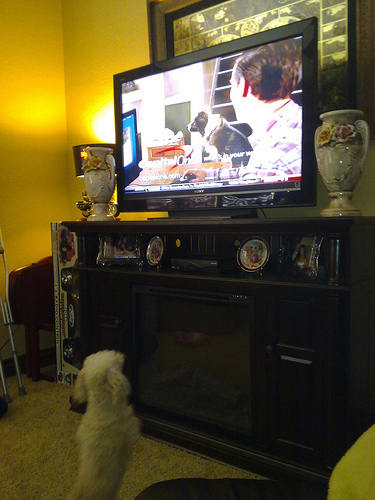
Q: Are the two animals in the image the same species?
A: Yes, all the animals are dogs.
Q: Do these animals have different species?
A: No, all the animals are dogs.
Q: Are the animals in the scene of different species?
A: No, all the animals are dogs.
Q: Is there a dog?
A: Yes, there is a dog.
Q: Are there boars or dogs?
A: Yes, there is a dog.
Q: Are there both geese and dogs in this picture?
A: No, there is a dog but no geese.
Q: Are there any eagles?
A: No, there are no eagles.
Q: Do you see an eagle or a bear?
A: No, there are no eagles or bears.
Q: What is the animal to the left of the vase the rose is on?
A: The animal is a dog.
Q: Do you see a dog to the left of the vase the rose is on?
A: Yes, there is a dog to the left of the vase.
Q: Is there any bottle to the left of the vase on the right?
A: No, there is a dog to the left of the vase.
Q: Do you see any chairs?
A: Yes, there is a chair.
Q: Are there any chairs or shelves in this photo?
A: Yes, there is a chair.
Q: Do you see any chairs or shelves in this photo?
A: Yes, there is a chair.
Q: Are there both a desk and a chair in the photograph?
A: No, there is a chair but no desks.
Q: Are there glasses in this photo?
A: No, there are no glasses.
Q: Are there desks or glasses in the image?
A: No, there are no glasses or desks.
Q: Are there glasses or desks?
A: No, there are no glasses or desks.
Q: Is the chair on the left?
A: Yes, the chair is on the left of the image.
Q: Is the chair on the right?
A: No, the chair is on the left of the image.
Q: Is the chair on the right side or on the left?
A: The chair is on the left of the image.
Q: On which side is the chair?
A: The chair is on the left of the image.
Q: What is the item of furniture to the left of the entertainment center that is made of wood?
A: The piece of furniture is a chair.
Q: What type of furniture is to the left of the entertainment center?
A: The piece of furniture is a chair.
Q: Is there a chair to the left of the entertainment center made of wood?
A: Yes, there is a chair to the left of the entertainment center.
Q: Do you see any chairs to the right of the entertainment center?
A: No, the chair is to the left of the entertainment center.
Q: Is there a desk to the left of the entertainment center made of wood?
A: No, there is a chair to the left of the entertainment center.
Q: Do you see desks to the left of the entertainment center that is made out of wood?
A: No, there is a chair to the left of the entertainment center.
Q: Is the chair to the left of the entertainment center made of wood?
A: Yes, the chair is to the left of the entertainment center.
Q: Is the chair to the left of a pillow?
A: No, the chair is to the left of the entertainment center.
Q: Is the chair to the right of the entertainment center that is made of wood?
A: No, the chair is to the left of the entertainment center.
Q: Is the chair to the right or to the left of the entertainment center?
A: The chair is to the left of the entertainment center.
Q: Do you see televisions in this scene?
A: Yes, there is a television.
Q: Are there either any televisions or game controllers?
A: Yes, there is a television.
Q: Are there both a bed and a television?
A: No, there is a television but no beds.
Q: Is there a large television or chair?
A: Yes, there is a large television.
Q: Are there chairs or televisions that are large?
A: Yes, the television is large.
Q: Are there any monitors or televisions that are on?
A: Yes, the television is on.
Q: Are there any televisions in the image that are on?
A: Yes, there is a television that is on.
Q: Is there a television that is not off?
A: Yes, there is a television that is on.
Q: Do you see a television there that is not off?
A: Yes, there is a television that is on .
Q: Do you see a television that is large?
A: Yes, there is a large television.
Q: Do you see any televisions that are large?
A: Yes, there is a television that is large.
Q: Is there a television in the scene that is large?
A: Yes, there is a television that is large.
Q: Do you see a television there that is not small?
A: Yes, there is a large television.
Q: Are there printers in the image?
A: No, there are no printers.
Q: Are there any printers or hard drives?
A: No, there are no printers or hard drives.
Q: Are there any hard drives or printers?
A: No, there are no printers or hard drives.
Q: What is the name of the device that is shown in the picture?
A: The device is a television.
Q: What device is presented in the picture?
A: The device is a television.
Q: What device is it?
A: The device is a television.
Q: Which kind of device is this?
A: This is a television.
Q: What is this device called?
A: This is a television.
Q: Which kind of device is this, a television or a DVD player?
A: This is a television.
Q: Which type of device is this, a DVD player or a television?
A: This is a television.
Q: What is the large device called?
A: The device is a television.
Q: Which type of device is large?
A: The device is a television.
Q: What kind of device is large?
A: The device is a television.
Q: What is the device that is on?
A: The device is a television.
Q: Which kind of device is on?
A: The device is a television.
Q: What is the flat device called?
A: The device is a television.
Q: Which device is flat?
A: The device is a television.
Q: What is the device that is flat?
A: The device is a television.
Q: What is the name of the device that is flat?
A: The device is a television.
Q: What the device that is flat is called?
A: The device is a television.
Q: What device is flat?
A: The device is a television.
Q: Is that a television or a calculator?
A: That is a television.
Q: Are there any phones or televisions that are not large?
A: No, there is a television but it is large.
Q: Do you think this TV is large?
A: Yes, the TV is large.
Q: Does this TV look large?
A: Yes, the TV is large.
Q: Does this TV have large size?
A: Yes, the TV is large.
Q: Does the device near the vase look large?
A: Yes, the TV is large.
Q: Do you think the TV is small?
A: No, the TV is large.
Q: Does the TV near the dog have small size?
A: No, the television is large.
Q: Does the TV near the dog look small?
A: No, the television is large.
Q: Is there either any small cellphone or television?
A: No, there is a television but it is large.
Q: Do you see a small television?
A: No, there is a television but it is large.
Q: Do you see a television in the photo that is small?
A: No, there is a television but it is large.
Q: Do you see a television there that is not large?
A: No, there is a television but it is large.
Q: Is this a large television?
A: Yes, this is a large television.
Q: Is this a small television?
A: No, this is a large television.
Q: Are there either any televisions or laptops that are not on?
A: No, there is a television but it is on.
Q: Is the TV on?
A: Yes, the TV is on.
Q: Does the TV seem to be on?
A: Yes, the TV is on.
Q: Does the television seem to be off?
A: No, the television is on.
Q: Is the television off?
A: No, the television is on.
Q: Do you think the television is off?
A: No, the television is on.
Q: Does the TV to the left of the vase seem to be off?
A: No, the TV is on.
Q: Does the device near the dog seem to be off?
A: No, the TV is on.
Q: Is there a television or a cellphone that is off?
A: No, there is a television but it is on.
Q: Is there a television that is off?
A: No, there is a television but it is on.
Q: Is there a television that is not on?
A: No, there is a television but it is on.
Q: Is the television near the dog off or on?
A: The television is on.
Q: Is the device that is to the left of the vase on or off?
A: The television is on.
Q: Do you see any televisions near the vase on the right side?
A: Yes, there is a television near the vase.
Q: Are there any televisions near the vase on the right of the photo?
A: Yes, there is a television near the vase.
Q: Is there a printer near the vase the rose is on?
A: No, there is a television near the vase.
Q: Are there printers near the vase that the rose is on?
A: No, there is a television near the vase.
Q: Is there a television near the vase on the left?
A: Yes, there is a television near the vase.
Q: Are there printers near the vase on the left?
A: No, there is a television near the vase.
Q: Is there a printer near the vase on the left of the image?
A: No, there is a television near the vase.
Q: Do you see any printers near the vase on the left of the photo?
A: No, there is a television near the vase.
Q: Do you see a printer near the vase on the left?
A: No, there is a television near the vase.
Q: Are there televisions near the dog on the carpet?
A: Yes, there is a television near the dog.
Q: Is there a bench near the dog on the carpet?
A: No, there is a television near the dog.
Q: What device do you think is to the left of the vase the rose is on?
A: The device is a television.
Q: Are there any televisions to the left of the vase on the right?
A: Yes, there is a television to the left of the vase.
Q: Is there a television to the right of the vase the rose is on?
A: No, the television is to the left of the vase.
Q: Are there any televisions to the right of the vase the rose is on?
A: No, the television is to the left of the vase.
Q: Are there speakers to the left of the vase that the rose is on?
A: No, there is a television to the left of the vase.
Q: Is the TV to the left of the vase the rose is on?
A: Yes, the TV is to the left of the vase.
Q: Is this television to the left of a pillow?
A: No, the television is to the left of the vase.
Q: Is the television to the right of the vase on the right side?
A: No, the television is to the left of the vase.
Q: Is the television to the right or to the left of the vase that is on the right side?
A: The television is to the left of the vase.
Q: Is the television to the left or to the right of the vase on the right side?
A: The television is to the left of the vase.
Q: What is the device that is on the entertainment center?
A: The device is a television.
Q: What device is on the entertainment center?
A: The device is a television.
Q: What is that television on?
A: The television is on the entertainment center.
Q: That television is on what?
A: The television is on the entertainment center.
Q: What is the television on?
A: The television is on the entertainment center.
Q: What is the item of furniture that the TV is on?
A: The piece of furniture is an entertainment center.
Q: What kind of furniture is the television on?
A: The TV is on the entertainment center.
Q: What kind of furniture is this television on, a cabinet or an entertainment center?
A: The television is on an entertainment center.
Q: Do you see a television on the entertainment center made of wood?
A: Yes, there is a television on the entertainment center.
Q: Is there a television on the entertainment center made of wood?
A: Yes, there is a television on the entertainment center.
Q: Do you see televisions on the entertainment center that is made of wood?
A: Yes, there is a television on the entertainment center.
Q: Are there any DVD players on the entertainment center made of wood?
A: No, there is a television on the entertainment center.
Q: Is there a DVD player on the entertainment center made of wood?
A: No, there is a television on the entertainment center.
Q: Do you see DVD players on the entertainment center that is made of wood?
A: No, there is a television on the entertainment center.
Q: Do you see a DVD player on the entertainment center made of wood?
A: No, there is a television on the entertainment center.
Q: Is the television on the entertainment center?
A: Yes, the television is on the entertainment center.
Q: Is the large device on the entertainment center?
A: Yes, the television is on the entertainment center.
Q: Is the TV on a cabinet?
A: No, the TV is on the entertainment center.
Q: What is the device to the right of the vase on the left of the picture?
A: The device is a television.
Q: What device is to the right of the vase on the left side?
A: The device is a television.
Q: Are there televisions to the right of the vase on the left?
A: Yes, there is a television to the right of the vase.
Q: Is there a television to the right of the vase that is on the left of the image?
A: Yes, there is a television to the right of the vase.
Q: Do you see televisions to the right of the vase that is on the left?
A: Yes, there is a television to the right of the vase.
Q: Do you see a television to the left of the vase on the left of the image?
A: No, the television is to the right of the vase.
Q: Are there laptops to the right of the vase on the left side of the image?
A: No, there is a television to the right of the vase.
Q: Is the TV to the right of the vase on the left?
A: Yes, the TV is to the right of the vase.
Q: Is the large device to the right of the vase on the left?
A: Yes, the TV is to the right of the vase.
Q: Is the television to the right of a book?
A: No, the television is to the right of the vase.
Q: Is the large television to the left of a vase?
A: No, the television is to the right of a vase.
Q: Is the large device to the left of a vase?
A: No, the television is to the right of a vase.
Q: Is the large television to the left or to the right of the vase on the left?
A: The television is to the right of the vase.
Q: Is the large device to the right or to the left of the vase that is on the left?
A: The television is to the right of the vase.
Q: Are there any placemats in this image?
A: No, there are no placemats.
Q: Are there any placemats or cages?
A: No, there are no placemats or cages.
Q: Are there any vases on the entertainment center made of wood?
A: Yes, there is a vase on the entertainment center.